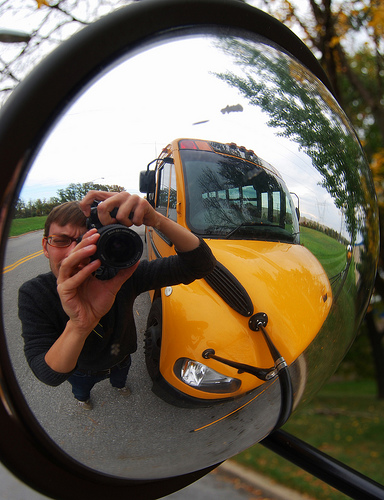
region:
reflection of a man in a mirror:
[17, 202, 215, 413]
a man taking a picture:
[18, 192, 215, 411]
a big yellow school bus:
[140, 139, 334, 410]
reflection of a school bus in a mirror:
[143, 137, 332, 404]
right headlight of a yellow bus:
[173, 354, 242, 395]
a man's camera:
[85, 196, 142, 279]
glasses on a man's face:
[45, 235, 79, 249]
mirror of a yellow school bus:
[0, 2, 382, 496]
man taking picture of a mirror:
[14, 192, 214, 405]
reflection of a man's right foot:
[75, 394, 96, 413]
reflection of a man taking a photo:
[24, 205, 167, 413]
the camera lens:
[65, 213, 152, 281]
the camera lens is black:
[80, 223, 149, 277]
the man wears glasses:
[37, 233, 98, 260]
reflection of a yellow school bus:
[123, 129, 328, 401]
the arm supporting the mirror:
[252, 419, 382, 495]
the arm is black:
[257, 430, 376, 498]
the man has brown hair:
[43, 204, 112, 230]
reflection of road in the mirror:
[37, 393, 294, 475]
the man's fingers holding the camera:
[72, 229, 108, 282]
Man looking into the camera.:
[40, 196, 164, 301]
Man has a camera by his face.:
[47, 211, 156, 302]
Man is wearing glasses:
[52, 227, 100, 265]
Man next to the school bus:
[72, 156, 304, 369]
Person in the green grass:
[342, 235, 354, 274]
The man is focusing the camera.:
[52, 206, 148, 290]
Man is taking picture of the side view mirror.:
[26, 75, 283, 301]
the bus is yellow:
[171, 142, 286, 275]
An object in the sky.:
[213, 91, 260, 124]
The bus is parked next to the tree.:
[303, 39, 381, 328]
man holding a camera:
[12, 162, 162, 312]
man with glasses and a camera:
[42, 187, 150, 276]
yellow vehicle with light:
[181, 316, 261, 390]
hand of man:
[50, 263, 102, 318]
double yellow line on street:
[14, 251, 38, 271]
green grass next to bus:
[334, 383, 369, 432]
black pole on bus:
[295, 421, 366, 481]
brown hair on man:
[52, 199, 81, 224]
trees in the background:
[47, 183, 73, 205]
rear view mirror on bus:
[135, 160, 165, 191]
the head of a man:
[38, 202, 96, 285]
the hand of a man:
[52, 227, 139, 330]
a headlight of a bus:
[168, 348, 246, 397]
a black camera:
[80, 194, 145, 291]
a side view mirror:
[133, 152, 162, 195]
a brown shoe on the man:
[74, 392, 96, 412]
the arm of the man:
[14, 278, 89, 393]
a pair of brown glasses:
[40, 230, 86, 249]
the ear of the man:
[39, 234, 52, 258]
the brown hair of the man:
[37, 200, 102, 242]